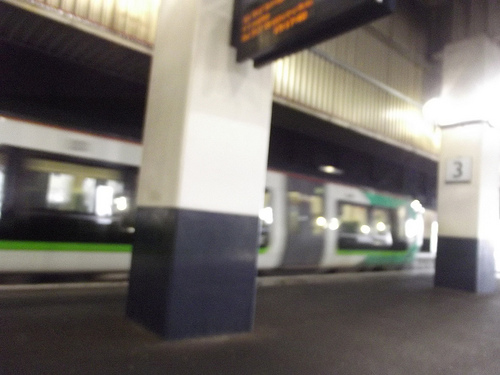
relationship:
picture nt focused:
[10, 19, 449, 320] [348, 223, 467, 319]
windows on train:
[20, 168, 123, 236] [8, 112, 415, 265]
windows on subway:
[20, 168, 123, 236] [28, 152, 398, 232]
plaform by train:
[22, 235, 444, 358] [8, 112, 415, 265]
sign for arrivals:
[226, 7, 446, 73] [247, 12, 310, 24]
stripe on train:
[1, 227, 140, 265] [8, 112, 415, 265]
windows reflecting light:
[20, 168, 123, 236] [314, 200, 410, 249]